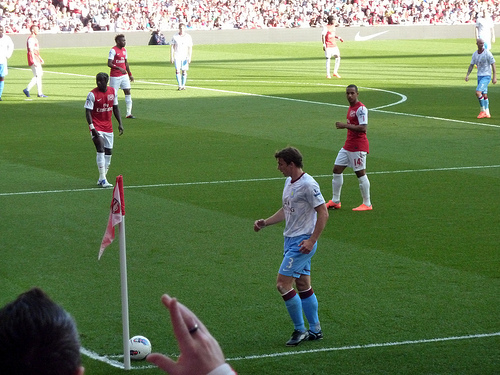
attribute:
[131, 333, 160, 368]
soccer ball — white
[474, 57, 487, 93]
uniform — blue, white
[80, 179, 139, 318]
flag — red, white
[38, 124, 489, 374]
field — green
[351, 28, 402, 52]
logo — nike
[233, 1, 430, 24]
fans — crowd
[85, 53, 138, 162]
uniforms — red, white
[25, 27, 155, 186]
men — playing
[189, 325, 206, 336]
ring — metal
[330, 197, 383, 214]
cleats — orange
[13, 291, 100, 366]
cameraman — filiming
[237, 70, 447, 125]
lines — white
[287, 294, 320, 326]
socks — blue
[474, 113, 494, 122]
shoes — orange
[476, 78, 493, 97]
pants — blue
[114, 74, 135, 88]
pants — white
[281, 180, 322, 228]
shirt — white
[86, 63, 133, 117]
shirts — red, white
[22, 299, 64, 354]
head — back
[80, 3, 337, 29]
spectators — sitting, watching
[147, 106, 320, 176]
grass — green, short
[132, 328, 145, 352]
ball — white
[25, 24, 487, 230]
people — playing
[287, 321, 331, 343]
shoes — black